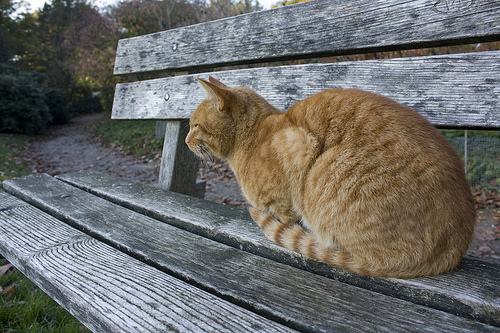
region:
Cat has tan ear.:
[194, 73, 241, 119]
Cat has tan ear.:
[203, 68, 233, 87]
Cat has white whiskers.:
[193, 140, 234, 177]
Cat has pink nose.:
[166, 130, 193, 148]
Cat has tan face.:
[186, 85, 223, 115]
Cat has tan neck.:
[240, 87, 297, 135]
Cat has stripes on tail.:
[254, 202, 328, 272]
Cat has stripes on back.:
[312, 80, 387, 130]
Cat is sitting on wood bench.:
[212, 121, 413, 288]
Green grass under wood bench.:
[23, 279, 45, 324]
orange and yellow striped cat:
[176, 68, 486, 283]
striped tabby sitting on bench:
[173, 68, 480, 289]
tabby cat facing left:
[170, 70, 483, 285]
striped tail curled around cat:
[236, 193, 463, 278]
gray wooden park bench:
[3, 3, 497, 332]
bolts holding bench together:
[158, 40, 182, 104]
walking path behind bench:
[25, 99, 499, 267]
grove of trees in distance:
[0, 2, 498, 135]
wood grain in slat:
[1, 190, 300, 331]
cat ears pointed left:
[193, 68, 237, 119]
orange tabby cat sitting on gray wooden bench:
[164, 69, 490, 281]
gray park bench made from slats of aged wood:
[1, 0, 498, 329]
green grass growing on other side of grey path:
[2, 98, 167, 325]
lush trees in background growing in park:
[11, 0, 230, 162]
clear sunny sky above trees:
[8, 0, 280, 17]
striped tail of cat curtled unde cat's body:
[231, 198, 373, 268]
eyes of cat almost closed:
[188, 121, 199, 131]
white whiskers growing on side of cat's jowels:
[193, 136, 215, 178]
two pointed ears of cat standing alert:
[201, 75, 233, 113]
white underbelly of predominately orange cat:
[276, 202, 348, 252]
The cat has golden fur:
[167, 66, 481, 283]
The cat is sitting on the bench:
[167, 52, 479, 311]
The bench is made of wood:
[12, 123, 474, 323]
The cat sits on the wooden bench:
[151, 63, 490, 315]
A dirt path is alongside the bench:
[28, 84, 110, 166]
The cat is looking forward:
[171, 56, 282, 178]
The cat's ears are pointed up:
[176, 52, 239, 116]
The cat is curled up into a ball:
[175, 55, 481, 300]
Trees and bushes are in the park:
[10, 7, 110, 143]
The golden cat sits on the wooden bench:
[164, 64, 477, 323]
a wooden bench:
[1, 17, 489, 319]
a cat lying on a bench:
[143, 65, 495, 320]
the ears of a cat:
[193, 73, 233, 104]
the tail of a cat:
[242, 197, 348, 272]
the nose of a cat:
[180, 135, 193, 147]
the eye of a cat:
[186, 120, 199, 132]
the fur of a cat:
[338, 115, 424, 242]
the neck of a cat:
[233, 90, 270, 168]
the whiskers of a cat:
[195, 139, 216, 174]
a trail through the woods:
[21, 95, 126, 170]